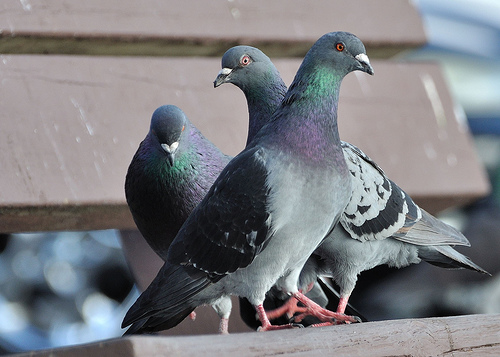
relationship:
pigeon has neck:
[283, 23, 380, 165] [260, 51, 346, 172]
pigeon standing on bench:
[124, 104, 368, 335] [4, 4, 484, 352]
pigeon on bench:
[124, 104, 368, 335] [15, 76, 465, 355]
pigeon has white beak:
[124, 104, 368, 329] [161, 142, 178, 151]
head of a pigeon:
[303, 30, 373, 77] [124, 104, 368, 335]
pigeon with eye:
[124, 104, 368, 335] [335, 42, 344, 51]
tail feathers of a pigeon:
[399, 191, 492, 279] [211, 37, 492, 319]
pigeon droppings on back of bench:
[124, 104, 368, 335] [55, 11, 463, 346]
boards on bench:
[41, 31, 478, 248] [61, 243, 393, 355]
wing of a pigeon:
[322, 132, 476, 259] [207, 40, 499, 336]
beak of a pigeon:
[350, 50, 376, 75] [124, 104, 368, 335]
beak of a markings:
[350, 50, 376, 75] [349, 160, 393, 227]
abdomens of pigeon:
[272, 160, 345, 268] [124, 104, 368, 335]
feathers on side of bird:
[343, 153, 403, 236] [114, 29, 380, 350]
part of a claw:
[313, 300, 320, 312] [285, 293, 363, 331]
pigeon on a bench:
[124, 104, 368, 335] [4, 4, 484, 352]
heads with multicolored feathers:
[96, 23, 383, 186] [274, 59, 353, 179]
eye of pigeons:
[334, 40, 346, 53] [176, 5, 360, 248]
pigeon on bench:
[193, 65, 371, 233] [286, 316, 356, 355]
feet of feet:
[256, 303, 303, 334] [286, 285, 362, 321]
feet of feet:
[256, 303, 303, 334] [306, 292, 353, 327]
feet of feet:
[256, 303, 303, 334] [258, 294, 311, 320]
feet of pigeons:
[256, 303, 303, 334] [119, 100, 319, 323]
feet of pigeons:
[256, 303, 303, 334] [208, 45, 494, 324]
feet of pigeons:
[256, 303, 303, 334] [108, 25, 374, 337]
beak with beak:
[350, 50, 375, 76] [214, 60, 238, 90]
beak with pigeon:
[350, 50, 375, 76] [124, 104, 368, 335]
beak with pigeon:
[350, 50, 375, 76] [211, 37, 492, 319]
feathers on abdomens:
[270, 167, 351, 274] [272, 181, 335, 267]